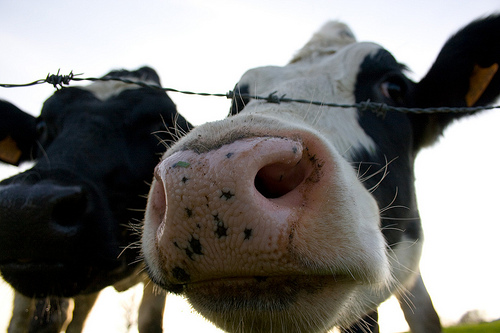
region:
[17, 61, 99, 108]
a wire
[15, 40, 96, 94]
a wire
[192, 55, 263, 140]
a wire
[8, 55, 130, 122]
a wire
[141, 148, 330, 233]
two pink nostrils of black and white cow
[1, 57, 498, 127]
metal barbed wire fence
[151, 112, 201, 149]
white whiskers of black and white cow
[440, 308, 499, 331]
patch of green grass in horizon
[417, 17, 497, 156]
one black and brown cow ear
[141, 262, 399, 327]
one cow mouth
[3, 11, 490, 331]
close up of two cows looking down through a barbed wire fence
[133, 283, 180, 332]
one cow leg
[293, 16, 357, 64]
one white hump between cow's eyes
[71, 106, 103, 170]
black fur of black and white cow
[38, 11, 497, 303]
large head of cow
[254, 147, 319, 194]
front pink nostril of cow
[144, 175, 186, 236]
other front nostril of cow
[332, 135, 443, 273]
whiskers on cows face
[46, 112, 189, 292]
whiskers on side of face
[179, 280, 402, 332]
chin whiskers on cow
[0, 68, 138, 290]
second black cow looking straight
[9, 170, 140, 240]
large nostril of cow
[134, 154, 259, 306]
black dots on front of nose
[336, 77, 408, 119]
black and white eye of cow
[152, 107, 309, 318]
Cows nose is dirty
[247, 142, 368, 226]
Dirt in cows nostril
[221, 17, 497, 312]
Cow has a white and black face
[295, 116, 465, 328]
Cow has short whiskers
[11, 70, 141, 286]
Cow is black with white accent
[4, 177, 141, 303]
Cow has a black nose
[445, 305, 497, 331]
Green grass in background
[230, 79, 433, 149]
Barbed wire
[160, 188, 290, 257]
Black spots on pink nose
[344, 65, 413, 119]
Cows large eye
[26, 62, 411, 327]
two big cows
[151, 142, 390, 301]
cow has white nose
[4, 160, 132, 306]
cow has black nose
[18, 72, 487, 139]
barbed wire fence in front of cows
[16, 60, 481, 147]
fence keeps cows from escaping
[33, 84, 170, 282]
cow has all black face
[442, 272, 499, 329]
grass behind the cows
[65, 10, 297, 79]
sky is very clear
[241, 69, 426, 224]
cow has black and white face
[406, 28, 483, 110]
cow has black ear